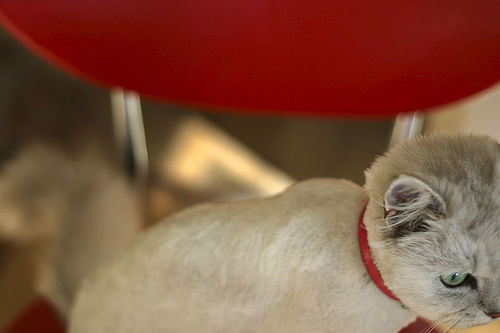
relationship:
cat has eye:
[68, 133, 500, 332] [439, 270, 471, 285]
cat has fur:
[68, 133, 500, 332] [277, 253, 327, 295]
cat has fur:
[68, 133, 500, 332] [2, 130, 499, 332]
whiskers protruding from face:
[417, 306, 466, 331] [392, 225, 498, 331]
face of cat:
[392, 225, 498, 331] [68, 133, 500, 332]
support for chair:
[113, 86, 158, 186] [2, 0, 498, 118]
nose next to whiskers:
[478, 302, 499, 321] [423, 308, 478, 331]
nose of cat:
[478, 302, 499, 321] [68, 125, 495, 331]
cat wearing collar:
[68, 125, 495, 331] [345, 193, 410, 305]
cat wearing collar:
[68, 125, 495, 331] [347, 196, 420, 323]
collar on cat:
[351, 209, 401, 290] [266, 163, 494, 280]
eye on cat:
[437, 270, 475, 293] [68, 125, 495, 331]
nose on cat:
[478, 302, 499, 321] [68, 125, 495, 331]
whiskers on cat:
[417, 306, 466, 331] [68, 125, 495, 331]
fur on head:
[424, 146, 481, 186] [360, 131, 499, 331]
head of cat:
[360, 131, 499, 331] [68, 125, 495, 331]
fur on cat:
[182, 204, 352, 291] [271, 154, 475, 321]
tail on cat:
[3, 138, 145, 319] [68, 133, 500, 332]